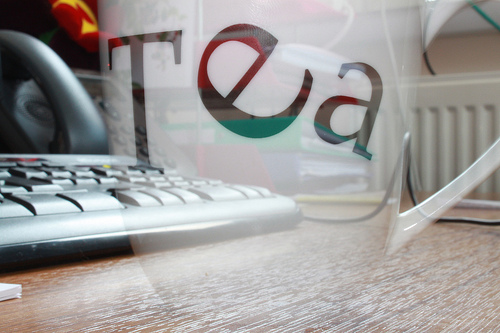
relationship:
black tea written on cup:
[97, 0, 424, 300] [93, 0, 498, 321]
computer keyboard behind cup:
[0, 153, 300, 264] [93, 0, 498, 321]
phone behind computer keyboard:
[4, 25, 206, 181] [0, 153, 300, 264]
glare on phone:
[95, 10, 494, 313] [4, 25, 206, 181]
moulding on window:
[203, 1, 490, 83] [203, 2, 410, 29]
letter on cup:
[105, 26, 182, 174] [93, 0, 498, 321]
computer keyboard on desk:
[0, 153, 300, 264] [0, 187, 499, 331]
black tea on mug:
[97, 0, 424, 300] [186, 2, 426, 247]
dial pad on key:
[103, 163, 113, 169] [90, 160, 126, 188]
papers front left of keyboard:
[1, 284, 22, 303] [1, 154, 295, 246]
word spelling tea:
[106, 20, 384, 177] [112, 26, 381, 186]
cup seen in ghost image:
[93, 0, 498, 321] [93, 0, 483, 316]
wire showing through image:
[299, 130, 498, 224] [95, 1, 485, 321]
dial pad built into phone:
[96, 98, 178, 169] [4, 25, 206, 181]